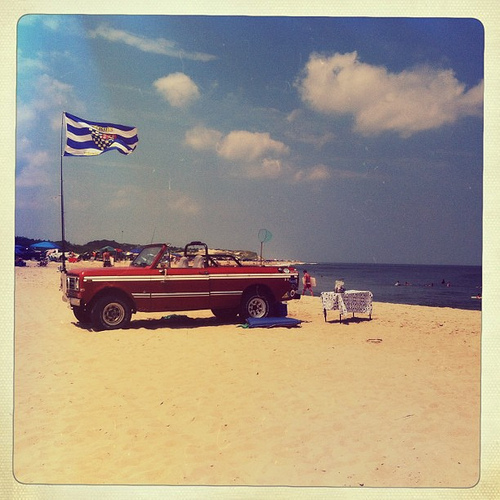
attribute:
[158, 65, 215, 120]
clouds — white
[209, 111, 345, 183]
clouds — white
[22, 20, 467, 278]
sky — blue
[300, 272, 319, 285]
board — white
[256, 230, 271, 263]
net — green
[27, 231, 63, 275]
umbrella — big, blue